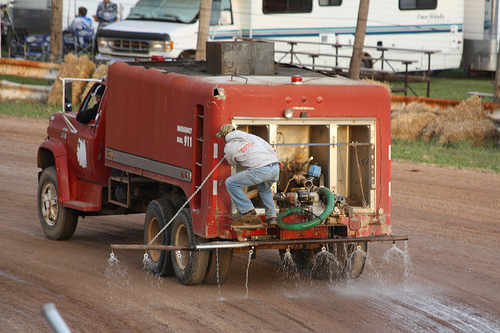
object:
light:
[290, 74, 303, 85]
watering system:
[187, 234, 414, 261]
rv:
[91, 0, 469, 79]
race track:
[0, 108, 497, 332]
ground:
[456, 140, 473, 160]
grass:
[393, 89, 500, 169]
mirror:
[64, 79, 73, 113]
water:
[101, 251, 137, 297]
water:
[138, 247, 168, 307]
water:
[211, 245, 227, 300]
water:
[243, 247, 255, 296]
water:
[278, 247, 302, 296]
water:
[346, 247, 383, 292]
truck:
[33, 37, 410, 285]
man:
[62, 5, 94, 52]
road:
[1, 112, 498, 332]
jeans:
[225, 161, 281, 219]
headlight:
[149, 41, 165, 55]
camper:
[109, 0, 462, 70]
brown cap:
[215, 124, 235, 138]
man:
[216, 123, 281, 225]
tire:
[36, 166, 78, 240]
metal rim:
[41, 181, 59, 226]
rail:
[304, 32, 496, 143]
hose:
[276, 186, 335, 230]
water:
[381, 239, 412, 283]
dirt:
[415, 216, 472, 311]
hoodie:
[223, 130, 278, 170]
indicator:
[290, 74, 303, 85]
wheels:
[145, 194, 231, 285]